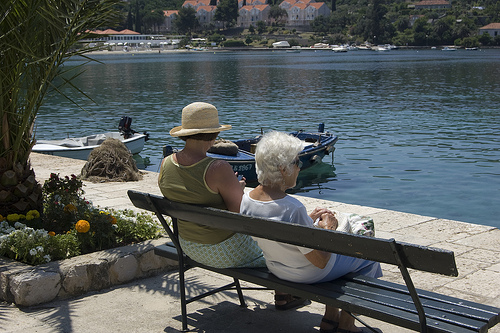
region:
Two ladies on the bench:
[123, 85, 498, 328]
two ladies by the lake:
[111, 40, 499, 328]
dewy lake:
[38, 0, 498, 95]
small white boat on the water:
[19, 90, 162, 170]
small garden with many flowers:
[0, 180, 165, 316]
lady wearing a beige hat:
[151, 95, 258, 306]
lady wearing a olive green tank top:
[128, 87, 247, 291]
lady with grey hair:
[238, 123, 385, 305]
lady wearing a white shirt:
[239, 130, 341, 293]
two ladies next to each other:
[141, 88, 393, 307]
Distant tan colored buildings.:
[153, 0, 329, 35]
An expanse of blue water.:
[31, 41, 498, 228]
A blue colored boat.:
[204, 119, 339, 182]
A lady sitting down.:
[246, 129, 385, 283]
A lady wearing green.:
[156, 99, 264, 267]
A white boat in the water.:
[32, 113, 149, 158]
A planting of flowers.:
[0, 169, 161, 270]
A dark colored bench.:
[126, 185, 498, 331]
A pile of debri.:
[78, 137, 149, 185]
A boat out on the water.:
[331, 43, 353, 55]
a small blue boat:
[30, 115, 146, 156]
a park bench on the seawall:
[361, 235, 496, 330]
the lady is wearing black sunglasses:
[280, 157, 302, 167]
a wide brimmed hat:
[168, 99, 231, 136]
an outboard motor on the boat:
[117, 113, 150, 143]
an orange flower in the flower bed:
[74, 218, 90, 235]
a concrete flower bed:
[0, 207, 153, 308]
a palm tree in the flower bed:
[1, 0, 97, 209]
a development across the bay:
[154, 0, 331, 32]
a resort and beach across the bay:
[67, 29, 206, 56]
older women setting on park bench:
[157, 100, 368, 331]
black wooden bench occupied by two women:
[124, 187, 497, 330]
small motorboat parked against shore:
[31, 113, 147, 156]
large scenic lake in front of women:
[28, 44, 498, 229]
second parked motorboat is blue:
[159, 128, 339, 172]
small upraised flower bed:
[2, 187, 194, 307]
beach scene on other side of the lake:
[69, 26, 372, 56]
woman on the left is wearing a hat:
[169, 102, 234, 141]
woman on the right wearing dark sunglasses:
[259, 142, 309, 169]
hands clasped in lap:
[302, 203, 342, 271]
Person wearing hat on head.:
[174, 99, 209, 134]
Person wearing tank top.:
[156, 152, 214, 237]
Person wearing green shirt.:
[159, 173, 211, 225]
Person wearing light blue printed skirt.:
[188, 233, 235, 266]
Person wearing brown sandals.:
[268, 289, 304, 327]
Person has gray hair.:
[255, 134, 304, 199]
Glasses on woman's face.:
[281, 153, 301, 173]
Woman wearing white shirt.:
[258, 202, 309, 289]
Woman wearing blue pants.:
[340, 249, 368, 275]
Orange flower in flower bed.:
[64, 216, 113, 245]